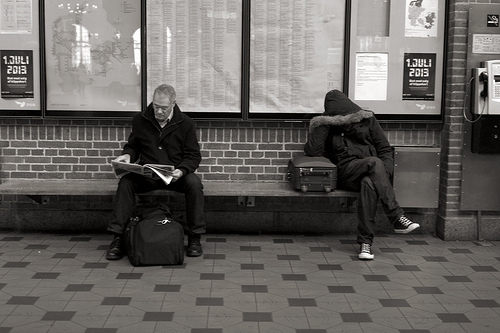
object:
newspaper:
[110, 160, 175, 186]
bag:
[121, 209, 185, 268]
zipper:
[158, 217, 171, 224]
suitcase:
[285, 157, 338, 193]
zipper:
[299, 167, 314, 172]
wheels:
[301, 185, 309, 193]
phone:
[463, 59, 499, 123]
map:
[405, 0, 439, 36]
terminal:
[0, 0, 499, 332]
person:
[304, 90, 422, 260]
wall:
[2, 3, 497, 241]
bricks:
[1, 1, 498, 220]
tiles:
[1, 228, 498, 332]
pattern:
[32, 261, 144, 291]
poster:
[402, 53, 435, 100]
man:
[108, 83, 204, 259]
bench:
[0, 178, 363, 206]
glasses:
[152, 104, 170, 112]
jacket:
[300, 89, 396, 174]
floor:
[0, 233, 497, 332]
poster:
[0, 49, 34, 99]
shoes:
[358, 243, 375, 259]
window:
[2, 1, 344, 111]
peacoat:
[121, 106, 202, 182]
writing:
[406, 59, 432, 78]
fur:
[308, 110, 374, 134]